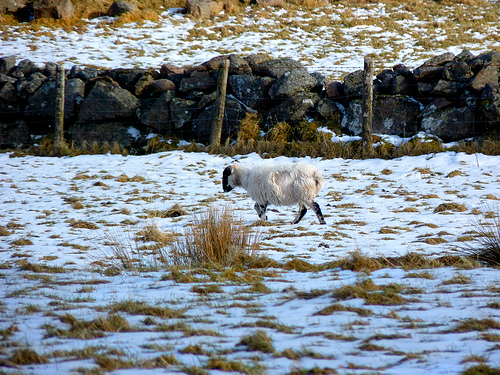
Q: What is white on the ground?
A: Snow.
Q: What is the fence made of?
A: Wood.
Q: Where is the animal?
A: In the field.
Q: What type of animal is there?
A: Sheep.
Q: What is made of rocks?
A: The wall.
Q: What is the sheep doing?
A: Walking.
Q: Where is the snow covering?
A: The ground.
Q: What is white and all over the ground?
A: Snow.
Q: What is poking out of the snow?
A: Grass.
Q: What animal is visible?
A: Sheep.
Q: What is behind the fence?
A: Rocks.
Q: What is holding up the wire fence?
A: Posts.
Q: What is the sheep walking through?
A: Snow.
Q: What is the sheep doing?
A: Walking.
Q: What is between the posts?
A: Wire.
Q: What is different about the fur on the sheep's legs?
A: It is black.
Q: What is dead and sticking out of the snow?
A: Grass.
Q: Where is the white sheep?
A: In the snow.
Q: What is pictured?
A: Animal.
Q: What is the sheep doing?
A: Walking.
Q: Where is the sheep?
A: Snowy field.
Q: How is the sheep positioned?
A: Standing.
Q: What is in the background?
A: Stone wall.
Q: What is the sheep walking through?
A: Snow.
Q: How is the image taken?
A: Good.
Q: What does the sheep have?
A: Fur.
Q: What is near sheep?
A: Thin grasses.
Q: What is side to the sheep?
A: Grasses.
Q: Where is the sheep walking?
A: Near stakes.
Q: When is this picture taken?
A: Daytime.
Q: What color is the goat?
A: White.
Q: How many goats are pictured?
A: One.